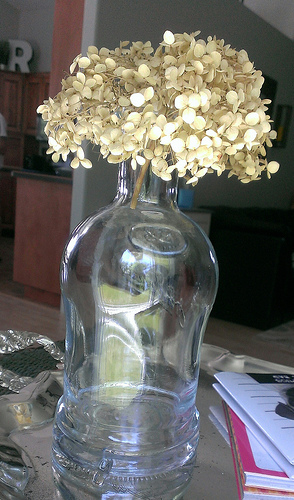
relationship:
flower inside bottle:
[35, 28, 281, 189] [37, 189, 233, 497]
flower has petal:
[35, 28, 281, 210] [161, 29, 175, 46]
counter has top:
[9, 167, 72, 308] [9, 167, 73, 183]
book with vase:
[214, 380, 289, 498] [56, 160, 228, 488]